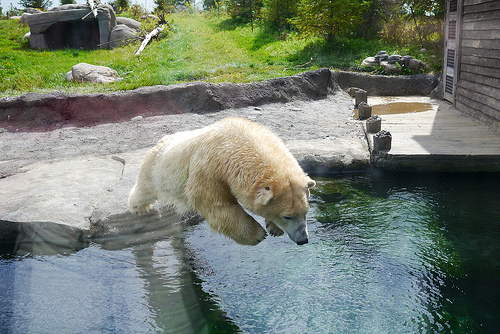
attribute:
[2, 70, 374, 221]
platform — rock, rocky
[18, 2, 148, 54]
cave — artificial, rocky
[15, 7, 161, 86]
boulders — large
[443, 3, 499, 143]
building — gray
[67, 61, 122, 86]
stone — large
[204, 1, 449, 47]
trees — tall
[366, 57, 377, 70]
rocks — gray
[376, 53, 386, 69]
rocks — gray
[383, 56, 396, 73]
rocks — gray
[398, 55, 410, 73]
rocks — gray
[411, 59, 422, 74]
rocks — gray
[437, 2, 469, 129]
door — wooden, slatted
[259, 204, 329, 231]
eyes — closed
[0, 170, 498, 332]
water — clear, calm, blue, large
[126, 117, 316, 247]
bear — leaping, diving, large, polar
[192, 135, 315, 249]
fur — brown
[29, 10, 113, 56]
cave — small 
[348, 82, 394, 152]
stones — straight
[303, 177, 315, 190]
ear — white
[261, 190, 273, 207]
ear — white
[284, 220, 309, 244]
snout — white, long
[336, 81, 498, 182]
deck — wooden 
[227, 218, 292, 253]
claws — black 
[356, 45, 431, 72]
rocks — pile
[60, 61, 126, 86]
rock — large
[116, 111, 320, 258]
polar bear — cream colored, large